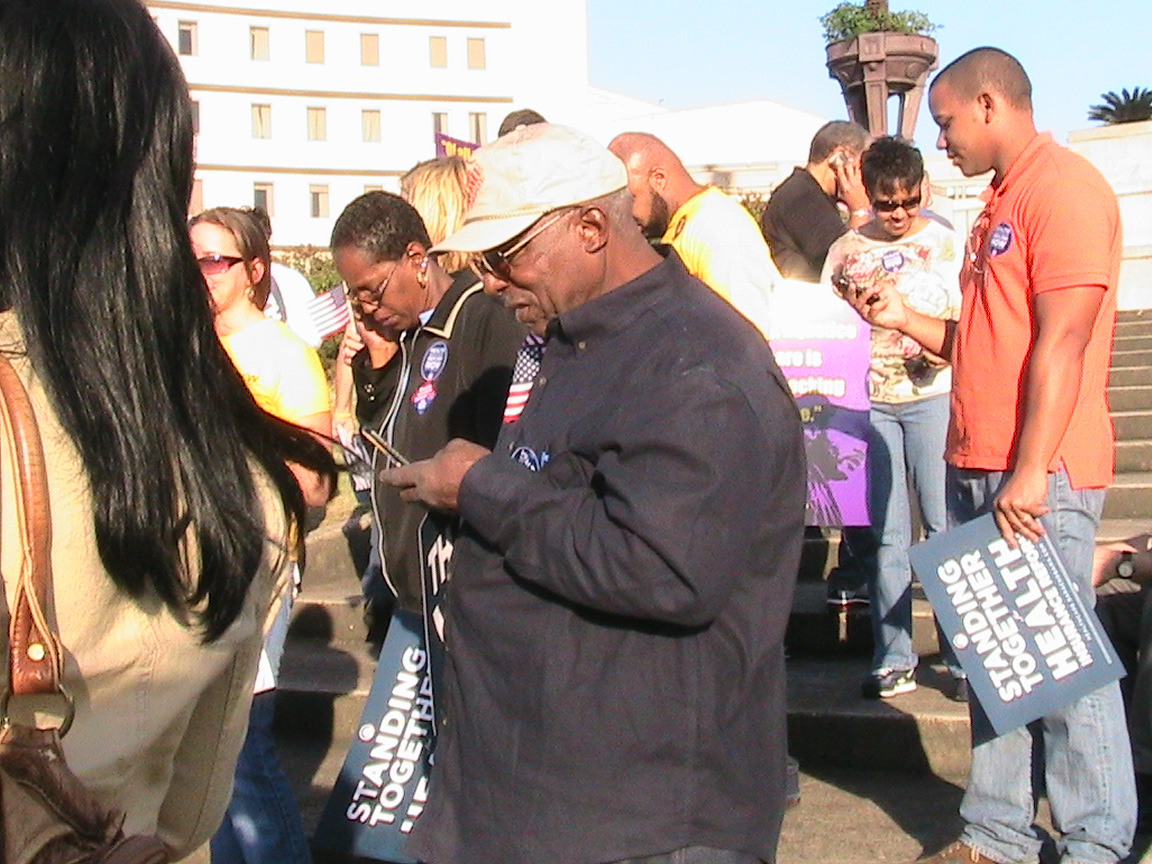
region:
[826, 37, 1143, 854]
Man looking at his cell phone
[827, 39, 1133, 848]
Man holding a sign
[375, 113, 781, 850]
Man wearing white cap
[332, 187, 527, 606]
Woman listening on phone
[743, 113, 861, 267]
Man listening on phone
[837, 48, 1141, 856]
Man wearing blue jeans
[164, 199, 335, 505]
Woman wearing yellow shirt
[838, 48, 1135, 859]
man wearing orange shirt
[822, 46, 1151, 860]
man wearing jeans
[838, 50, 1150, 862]
man holding a sign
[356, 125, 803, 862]
man looking at cell phone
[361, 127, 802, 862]
man wearing a cap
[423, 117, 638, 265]
the cap is beige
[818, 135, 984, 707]
woman is wearing sunglasses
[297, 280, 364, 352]
flag of the United States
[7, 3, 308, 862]
woman carrying a brown purse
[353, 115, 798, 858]
A man looking at his phone.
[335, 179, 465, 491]
A woman talking on a phone.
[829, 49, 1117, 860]
A man holding a sign.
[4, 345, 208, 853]
A brown strap of a womans purse.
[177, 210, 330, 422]
A lady in yellow wearing sunglasses.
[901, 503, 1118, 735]
A gray and white sign.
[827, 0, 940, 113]
A green plant in a brown pot.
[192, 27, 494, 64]
A roll of windows on a building.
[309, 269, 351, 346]
A American flag on a stick.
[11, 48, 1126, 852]
A group of people holding signs.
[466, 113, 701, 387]
the head ofa man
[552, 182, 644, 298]
the ear of a man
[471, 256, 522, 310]
the nose of a man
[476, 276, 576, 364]
the mouth of a man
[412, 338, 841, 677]
the arm of a man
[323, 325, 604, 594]
a man holding a phone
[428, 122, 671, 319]
a man wearing a hat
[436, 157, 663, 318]
a man wearing sunglasses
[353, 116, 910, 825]
a man wearing a shirt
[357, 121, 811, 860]
person using cell phone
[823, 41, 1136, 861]
person using cell phone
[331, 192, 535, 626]
person using cell phone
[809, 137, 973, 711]
person using cell phone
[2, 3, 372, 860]
person wearing brown bag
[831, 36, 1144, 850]
person holding blue sign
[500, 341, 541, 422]
American flag on black shirt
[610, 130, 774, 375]
man with bald head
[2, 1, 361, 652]
person with black hair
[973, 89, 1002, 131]
Ear of a man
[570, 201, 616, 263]
Ear of a man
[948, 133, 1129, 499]
Shirt on a man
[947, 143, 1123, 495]
Red shirt on a man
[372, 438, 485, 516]
Hand of a man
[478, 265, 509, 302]
Nose of a man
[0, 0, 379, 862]
A person is standing up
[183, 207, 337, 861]
A person is standing up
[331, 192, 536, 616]
A person is standing up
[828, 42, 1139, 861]
A person is standing up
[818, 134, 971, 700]
A person is standing up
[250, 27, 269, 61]
A window on a building.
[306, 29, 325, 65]
A window on a building.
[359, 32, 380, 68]
A window on a building.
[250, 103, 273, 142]
A window on a building.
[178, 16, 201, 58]
A window on a building.